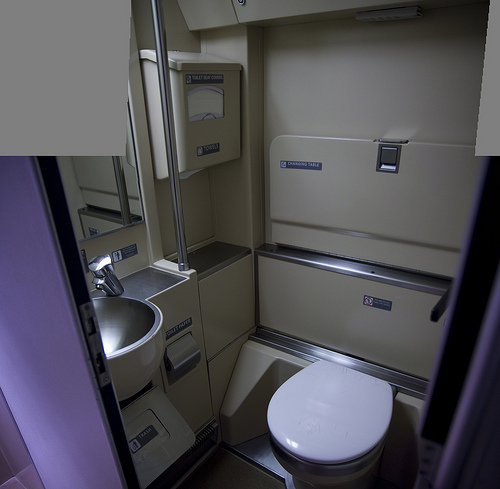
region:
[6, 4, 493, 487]
Compact bathroom suchc as in an rv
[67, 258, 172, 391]
Stainless steel sink bowl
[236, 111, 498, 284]
Pull down changing area for baby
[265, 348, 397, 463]
White toilet lid and seat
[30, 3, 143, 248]
Mirror behind sink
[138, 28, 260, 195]
Tan paper towel dispenser that is full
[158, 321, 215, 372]
Toilet paper roll holder filled with toilet paper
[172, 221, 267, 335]
Strategically placed trash can under paper towel dispenser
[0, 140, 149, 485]
Purple beam divider into room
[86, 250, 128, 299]
Shiny silver sink faucet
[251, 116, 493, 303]
fold out changing table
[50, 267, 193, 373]
small metal sink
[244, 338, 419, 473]
airplane toilet with lid down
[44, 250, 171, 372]
dry metal airplane sink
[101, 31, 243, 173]
toilet seat cover dispenser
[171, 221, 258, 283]
small trashcan for bathroom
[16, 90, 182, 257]
mirror above metal sink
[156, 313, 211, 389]
toilet paper dispenser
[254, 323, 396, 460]
lid of toilet in airport bathroom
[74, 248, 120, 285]
faucet for sink in airport bathroom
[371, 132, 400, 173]
Small part of silver metal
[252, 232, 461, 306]
Small part of silver metal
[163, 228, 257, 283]
Small part of silver metal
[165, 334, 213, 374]
Small part of silver metal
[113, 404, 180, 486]
Small part of silver metal trashcan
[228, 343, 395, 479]
Small white toilet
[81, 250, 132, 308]
Small silver sink faucet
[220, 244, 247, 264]
Small part of silver metal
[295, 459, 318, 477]
Small part of silver metal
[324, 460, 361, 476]
Small part of silver metal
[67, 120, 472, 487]
A very small bathroom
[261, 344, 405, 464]
A white toilet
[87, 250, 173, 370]
A chrome and beige sink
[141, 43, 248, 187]
A beige hand towel holder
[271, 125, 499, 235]
A beige fold down changing table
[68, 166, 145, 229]
A long mirror with chrome trim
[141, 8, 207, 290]
A long chrome pole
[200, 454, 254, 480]
A beige colored floor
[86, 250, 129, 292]
A chrome faucet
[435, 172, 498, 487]
Lavendar colored walls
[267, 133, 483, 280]
closed changing table in bathroom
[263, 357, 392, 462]
white toilet seat in bathroom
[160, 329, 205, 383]
chrome cover on toilet dispenser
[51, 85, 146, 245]
clean mirror in bathroom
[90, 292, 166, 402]
round silver sink in bathroom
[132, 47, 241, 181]
paper towel with napkins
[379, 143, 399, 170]
chrome latch on changing table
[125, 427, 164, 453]
brown sign under bathroom sink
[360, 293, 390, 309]
brown sign behind toilet bowl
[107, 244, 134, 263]
brown sign behind silver sink